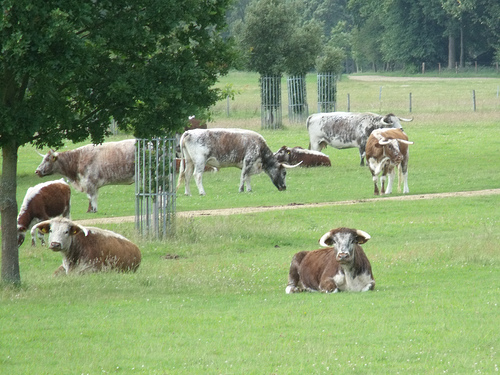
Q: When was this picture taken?
A: During the day.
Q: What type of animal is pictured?
A: Cows.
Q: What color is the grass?
A: Green.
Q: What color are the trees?
A: Green.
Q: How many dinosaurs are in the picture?
A: Zero.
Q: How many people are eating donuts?
A: Zero.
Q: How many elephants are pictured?
A: Zero.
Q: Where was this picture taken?
A: Near cows.